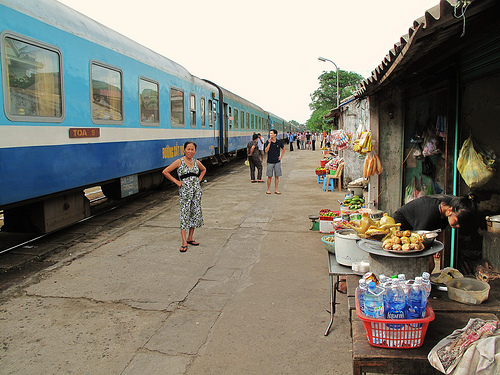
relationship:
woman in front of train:
[160, 142, 207, 251] [3, 1, 306, 246]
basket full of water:
[353, 281, 435, 349] [360, 272, 431, 345]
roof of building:
[350, 0, 485, 94] [356, 0, 498, 272]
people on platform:
[246, 128, 334, 195] [3, 132, 335, 372]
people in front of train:
[246, 128, 334, 195] [3, 1, 306, 246]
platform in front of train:
[3, 132, 335, 372] [3, 1, 306, 246]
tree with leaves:
[305, 70, 364, 130] [304, 70, 367, 133]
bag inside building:
[455, 133, 499, 188] [356, 0, 498, 272]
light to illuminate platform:
[315, 54, 340, 111] [3, 132, 335, 372]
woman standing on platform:
[160, 142, 207, 251] [3, 132, 335, 372]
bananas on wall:
[363, 153, 384, 179] [370, 79, 500, 254]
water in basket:
[360, 272, 431, 345] [353, 281, 435, 349]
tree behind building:
[305, 70, 364, 130] [324, 93, 363, 186]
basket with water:
[353, 281, 435, 349] [360, 272, 431, 345]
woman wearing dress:
[160, 142, 207, 251] [178, 157, 204, 230]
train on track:
[3, 1, 306, 246] [1, 139, 299, 272]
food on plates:
[353, 213, 426, 253] [334, 226, 445, 259]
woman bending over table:
[395, 188, 480, 230] [324, 235, 357, 336]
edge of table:
[324, 250, 356, 276] [324, 235, 357, 336]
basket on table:
[353, 281, 435, 349] [351, 309, 500, 375]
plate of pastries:
[356, 240, 446, 260] [382, 229, 428, 254]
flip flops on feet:
[178, 238, 201, 254] [180, 238, 199, 253]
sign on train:
[68, 126, 100, 139] [3, 1, 306, 246]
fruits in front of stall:
[315, 158, 334, 183] [324, 93, 363, 186]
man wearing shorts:
[264, 128, 285, 196] [265, 161, 283, 179]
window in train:
[1, 32, 66, 122] [3, 1, 306, 246]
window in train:
[88, 58, 126, 126] [3, 1, 306, 246]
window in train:
[138, 73, 161, 128] [3, 1, 306, 246]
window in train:
[169, 85, 186, 127] [3, 1, 306, 246]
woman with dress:
[160, 142, 207, 251] [178, 157, 204, 230]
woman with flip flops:
[160, 142, 207, 251] [178, 238, 201, 254]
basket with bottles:
[353, 281, 435, 349] [360, 272, 431, 345]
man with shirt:
[264, 128, 285, 196] [262, 140, 284, 162]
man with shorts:
[264, 128, 285, 196] [265, 161, 283, 179]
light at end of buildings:
[315, 54, 340, 111] [326, 3, 497, 277]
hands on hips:
[173, 178, 205, 186] [174, 178, 206, 192]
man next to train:
[264, 128, 285, 196] [3, 1, 306, 246]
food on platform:
[308, 128, 428, 254] [3, 132, 335, 372]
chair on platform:
[325, 159, 345, 193] [3, 132, 335, 372]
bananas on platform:
[343, 193, 366, 212] [3, 132, 335, 372]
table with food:
[324, 235, 357, 336] [353, 213, 426, 253]